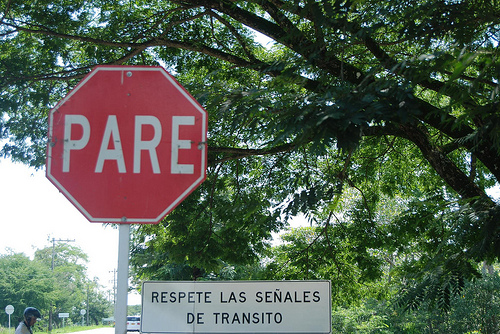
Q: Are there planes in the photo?
A: No, there are no planes.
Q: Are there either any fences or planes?
A: No, there are no planes or fences.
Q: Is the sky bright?
A: Yes, the sky is bright.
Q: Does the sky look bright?
A: Yes, the sky is bright.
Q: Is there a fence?
A: No, there are no fences.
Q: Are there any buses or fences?
A: No, there are no fences or buses.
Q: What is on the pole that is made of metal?
A: The sign is on the pole.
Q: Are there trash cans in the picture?
A: No, there are no trash cans.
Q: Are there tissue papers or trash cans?
A: No, there are no trash cans or tissue papers.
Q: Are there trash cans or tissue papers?
A: No, there are no trash cans or tissue papers.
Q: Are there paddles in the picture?
A: No, there are no paddles.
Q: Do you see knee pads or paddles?
A: No, there are no paddles or knee pads.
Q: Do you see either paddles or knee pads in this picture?
A: No, there are no paddles or knee pads.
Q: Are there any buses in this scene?
A: No, there are no buses.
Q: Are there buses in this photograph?
A: No, there are no buses.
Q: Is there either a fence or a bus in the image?
A: No, there are no buses or fences.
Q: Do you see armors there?
A: No, there are no armors.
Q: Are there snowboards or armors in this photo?
A: No, there are no armors or snowboards.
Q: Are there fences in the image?
A: No, there are no fences.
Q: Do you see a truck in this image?
A: No, there are no trucks.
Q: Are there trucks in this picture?
A: No, there are no trucks.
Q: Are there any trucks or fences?
A: No, there are no trucks or fences.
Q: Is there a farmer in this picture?
A: No, there are no farmers.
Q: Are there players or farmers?
A: No, there are no farmers or players.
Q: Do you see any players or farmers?
A: No, there are no farmers or players.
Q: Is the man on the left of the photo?
A: Yes, the man is on the left of the image.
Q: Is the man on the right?
A: No, the man is on the left of the image.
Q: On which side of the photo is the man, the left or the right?
A: The man is on the left of the image.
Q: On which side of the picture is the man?
A: The man is on the left of the image.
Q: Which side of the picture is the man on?
A: The man is on the left of the image.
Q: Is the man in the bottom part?
A: Yes, the man is in the bottom of the image.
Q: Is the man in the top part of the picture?
A: No, the man is in the bottom of the image.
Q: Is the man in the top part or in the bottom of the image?
A: The man is in the bottom of the image.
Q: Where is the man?
A: The man is on the road.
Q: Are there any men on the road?
A: Yes, there is a man on the road.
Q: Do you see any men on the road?
A: Yes, there is a man on the road.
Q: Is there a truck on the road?
A: No, there is a man on the road.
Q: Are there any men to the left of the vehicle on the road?
A: Yes, there is a man to the left of the car.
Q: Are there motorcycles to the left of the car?
A: No, there is a man to the left of the car.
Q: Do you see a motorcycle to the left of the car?
A: No, there is a man to the left of the car.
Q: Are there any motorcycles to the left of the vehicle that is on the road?
A: No, there is a man to the left of the car.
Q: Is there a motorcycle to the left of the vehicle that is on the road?
A: No, there is a man to the left of the car.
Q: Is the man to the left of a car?
A: Yes, the man is to the left of a car.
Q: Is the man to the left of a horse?
A: No, the man is to the left of a car.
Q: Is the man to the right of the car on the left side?
A: No, the man is to the left of the car.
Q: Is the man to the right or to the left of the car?
A: The man is to the left of the car.